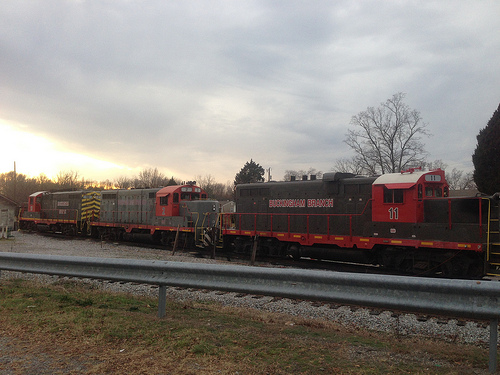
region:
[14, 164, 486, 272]
trains parked on the tracks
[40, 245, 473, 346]
the rail is grey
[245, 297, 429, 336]
the gravel is next to the tracks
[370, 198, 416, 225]
the number is black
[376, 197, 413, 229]
the number is 11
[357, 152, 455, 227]
the conductors car is red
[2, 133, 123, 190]
the sun is setting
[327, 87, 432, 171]
the tree is bare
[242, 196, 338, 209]
the letters are red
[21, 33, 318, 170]
the sky is overcast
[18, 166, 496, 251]
the train on the tracks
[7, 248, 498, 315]
the railing beside the tracks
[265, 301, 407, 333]
the gravel on the tracks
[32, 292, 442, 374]
the grass beside the tracks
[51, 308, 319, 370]
the grass is dry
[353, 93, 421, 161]
the tree without leaves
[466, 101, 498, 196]
the pine tree with green leaves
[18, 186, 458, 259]
the train is red and brown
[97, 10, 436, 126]
the sky is cloudy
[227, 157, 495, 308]
a train locomotive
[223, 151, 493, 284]
a train engine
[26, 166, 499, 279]
three train engines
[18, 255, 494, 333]
a metal guard rail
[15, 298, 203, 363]
brown and green grass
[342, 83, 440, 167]
a deciduous tree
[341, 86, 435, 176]
a deciduous tree with no foliage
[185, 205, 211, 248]
the ladder on the side of a train engine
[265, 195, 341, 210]
the name of a train line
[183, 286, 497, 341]
the edge of a railroad track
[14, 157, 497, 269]
train on the tracks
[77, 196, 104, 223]
black and yellow stripes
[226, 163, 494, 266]
front car is gray and red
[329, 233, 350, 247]
tiny yellow line on a red background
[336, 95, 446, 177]
tree with no leaves on it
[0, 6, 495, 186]
sky covered in gray clouds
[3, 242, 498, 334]
small metal railing along the train tracks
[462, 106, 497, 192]
dark, thick tree top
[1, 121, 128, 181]
sunlight shining through the clouds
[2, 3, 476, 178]
white and gray clouds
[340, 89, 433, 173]
tree without any leaves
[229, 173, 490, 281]
red and black train engine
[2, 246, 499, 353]
gray metal guard rail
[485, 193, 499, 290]
yellow metal ladder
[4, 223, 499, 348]
gravel path for train tracks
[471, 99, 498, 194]
tall evergreen tree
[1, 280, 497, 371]
dry dull green and brown patchy grass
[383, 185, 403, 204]
side windows on train engine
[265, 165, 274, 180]
utility poles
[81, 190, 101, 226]
yellow and black warning stripe on train car